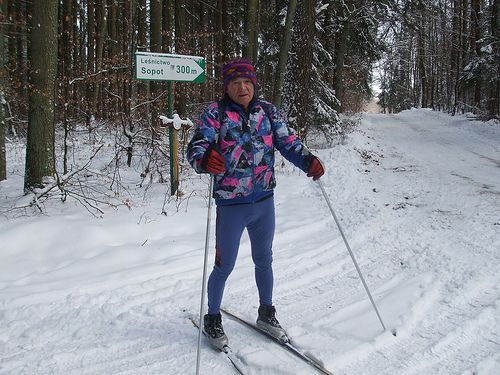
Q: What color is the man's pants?
A: Purple.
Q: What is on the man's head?
A: A hat.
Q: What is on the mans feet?
A: Skiies.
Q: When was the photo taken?
A: Day time.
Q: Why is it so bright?
A: Sun light.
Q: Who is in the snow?
A: A man.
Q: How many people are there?
A: One.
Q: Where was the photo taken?
A: Ski resort.